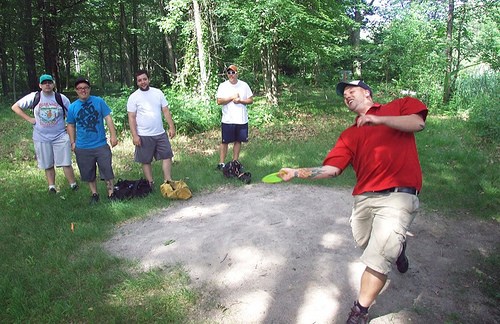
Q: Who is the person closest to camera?
A: Man.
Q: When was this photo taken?
A: Daytime.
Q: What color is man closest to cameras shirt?
A: Red.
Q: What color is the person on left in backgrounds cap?
A: Bluish-green.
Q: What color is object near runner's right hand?
A: Green.